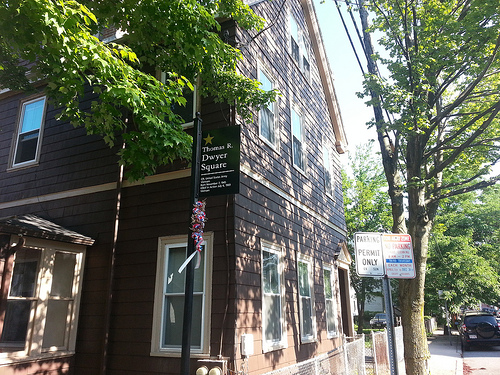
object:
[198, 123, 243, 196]
sign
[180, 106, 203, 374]
pole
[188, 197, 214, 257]
flowers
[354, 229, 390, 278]
sign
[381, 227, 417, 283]
sign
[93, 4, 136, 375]
pipe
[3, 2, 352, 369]
house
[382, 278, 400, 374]
post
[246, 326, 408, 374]
fence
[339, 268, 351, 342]
door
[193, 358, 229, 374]
meter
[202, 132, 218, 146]
star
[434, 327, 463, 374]
sidewalk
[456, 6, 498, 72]
branches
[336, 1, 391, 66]
power lines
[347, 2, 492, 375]
trees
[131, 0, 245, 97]
branch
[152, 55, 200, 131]
window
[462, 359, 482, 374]
leaves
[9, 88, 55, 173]
window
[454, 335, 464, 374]
curb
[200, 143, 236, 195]
writing